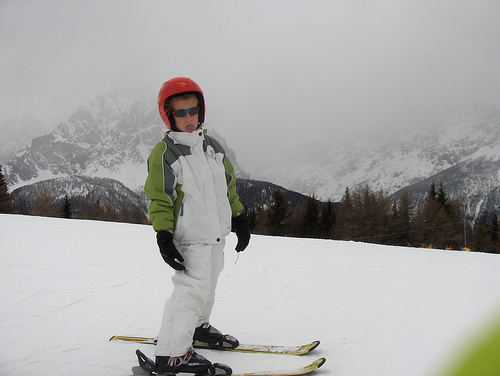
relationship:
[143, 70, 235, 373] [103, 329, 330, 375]
boy on skis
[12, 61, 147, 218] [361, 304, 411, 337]
mountains are covered in snow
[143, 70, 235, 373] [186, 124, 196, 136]
boy sticking out h tongue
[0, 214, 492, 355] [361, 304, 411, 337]
ground covered in snow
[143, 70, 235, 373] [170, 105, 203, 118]
boy wearing glasses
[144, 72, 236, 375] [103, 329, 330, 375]
girl on skis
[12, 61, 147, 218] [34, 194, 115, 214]
mountains behind trees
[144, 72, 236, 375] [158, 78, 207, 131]
girl wearing helmet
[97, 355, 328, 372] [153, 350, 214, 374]
ski has a ski shoes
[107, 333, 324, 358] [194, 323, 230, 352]
ski has a ski boot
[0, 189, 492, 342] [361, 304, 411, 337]
ground covered in snow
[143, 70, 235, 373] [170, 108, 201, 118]
boy wearing glasses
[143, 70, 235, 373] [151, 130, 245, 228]
boy wearing a jacket